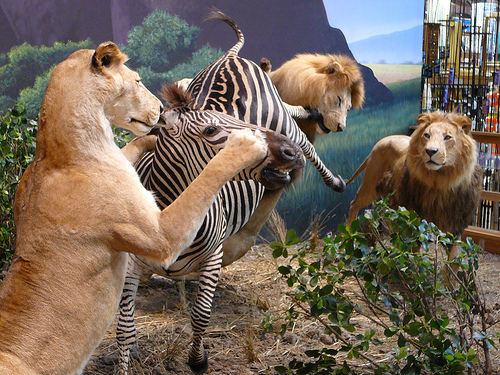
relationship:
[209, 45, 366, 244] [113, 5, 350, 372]
lion attacking zebra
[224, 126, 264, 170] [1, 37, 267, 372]
paw on lion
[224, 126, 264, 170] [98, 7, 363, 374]
paw on zebra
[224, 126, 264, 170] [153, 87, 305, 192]
paw on face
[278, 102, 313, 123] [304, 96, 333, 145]
zebra's leg in lion's mouth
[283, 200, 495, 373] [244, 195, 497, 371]
leaves on bush